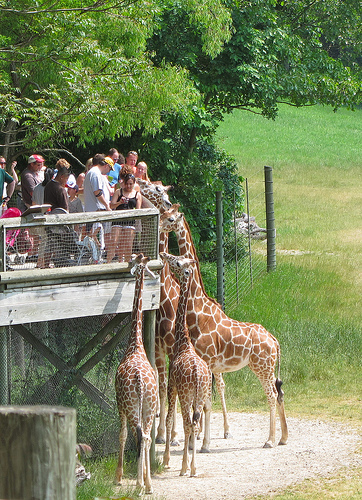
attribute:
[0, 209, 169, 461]
deck — wooden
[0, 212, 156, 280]
fencing — metal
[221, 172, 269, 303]
fence — wired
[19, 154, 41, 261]
man — white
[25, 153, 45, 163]
hat — red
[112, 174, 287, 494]
giraffes — white, brown, spotted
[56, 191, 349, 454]
giraffes — small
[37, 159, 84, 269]
girl — tank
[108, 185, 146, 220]
top — black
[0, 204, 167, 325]
deck — wooden